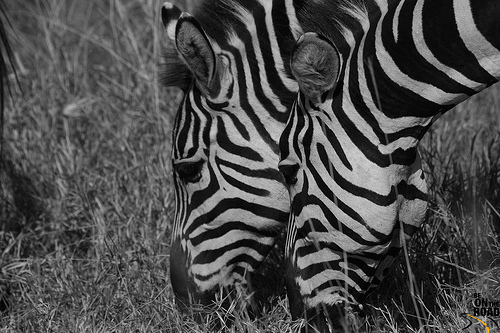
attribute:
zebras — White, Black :
[182, 27, 472, 313]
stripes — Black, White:
[375, 36, 468, 105]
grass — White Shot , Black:
[33, 232, 163, 314]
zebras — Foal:
[159, 2, 455, 304]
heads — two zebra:
[148, 20, 438, 314]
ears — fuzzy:
[167, 21, 351, 114]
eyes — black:
[176, 149, 216, 188]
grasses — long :
[199, 243, 462, 331]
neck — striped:
[239, 13, 469, 157]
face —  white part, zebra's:
[149, 138, 293, 313]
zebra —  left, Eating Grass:
[159, 8, 439, 318]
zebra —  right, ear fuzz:
[273, 12, 464, 332]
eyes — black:
[175, 148, 216, 193]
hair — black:
[295, 2, 376, 59]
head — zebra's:
[287, 3, 497, 318]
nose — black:
[159, 226, 210, 296]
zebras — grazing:
[141, 43, 407, 327]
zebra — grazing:
[155, 54, 433, 283]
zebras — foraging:
[175, 46, 450, 310]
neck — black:
[381, 84, 403, 117]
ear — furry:
[170, 9, 227, 105]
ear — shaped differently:
[159, 0, 185, 43]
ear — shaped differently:
[170, 10, 222, 100]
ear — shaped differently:
[286, 29, 345, 99]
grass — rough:
[1, 1, 484, 330]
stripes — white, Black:
[327, 52, 404, 211]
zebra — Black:
[138, 30, 433, 291]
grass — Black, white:
[21, 8, 447, 323]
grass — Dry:
[29, 23, 410, 305]